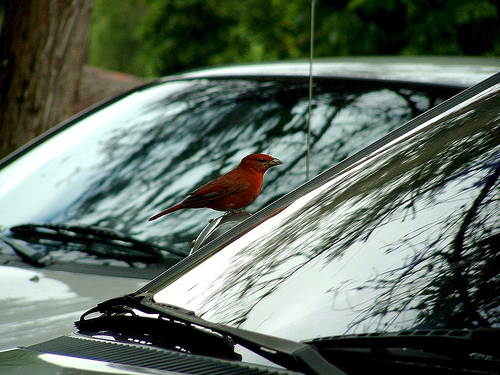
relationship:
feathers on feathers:
[145, 200, 182, 229] [147, 190, 201, 222]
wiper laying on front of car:
[6, 221, 191, 263] [6, 49, 490, 366]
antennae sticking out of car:
[252, 12, 371, 129] [0, 70, 498, 372]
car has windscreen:
[6, 49, 490, 366] [139, 86, 496, 370]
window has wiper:
[248, 205, 496, 325] [100, 288, 335, 371]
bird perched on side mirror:
[146, 152, 281, 221] [190, 209, 253, 253]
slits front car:
[70, 289, 328, 372] [109, 207, 483, 372]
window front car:
[1, 80, 484, 292] [1, 45, 498, 336]